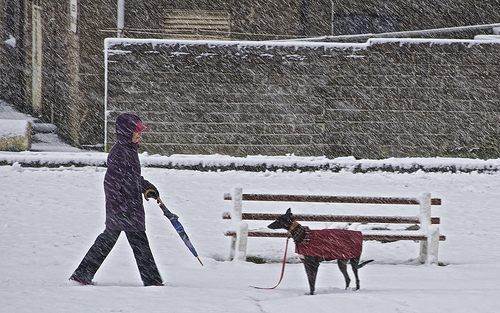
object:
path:
[1, 250, 498, 310]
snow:
[0, 147, 498, 309]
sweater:
[293, 228, 364, 260]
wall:
[105, 39, 498, 158]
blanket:
[293, 228, 363, 259]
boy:
[68, 111, 164, 287]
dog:
[266, 207, 374, 296]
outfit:
[287, 219, 363, 259]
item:
[143, 188, 205, 268]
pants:
[67, 223, 165, 286]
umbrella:
[143, 188, 204, 267]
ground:
[0, 169, 500, 313]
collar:
[287, 219, 299, 232]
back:
[228, 235, 236, 263]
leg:
[350, 257, 360, 291]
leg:
[336, 258, 351, 289]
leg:
[305, 256, 319, 295]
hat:
[134, 119, 147, 132]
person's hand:
[144, 188, 160, 200]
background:
[0, 0, 499, 164]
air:
[0, 0, 500, 313]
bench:
[221, 183, 446, 267]